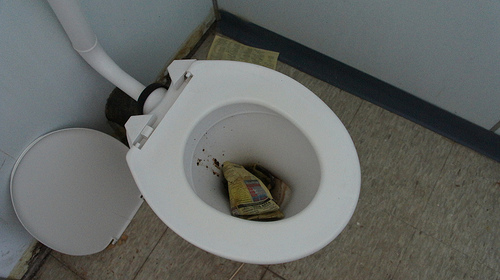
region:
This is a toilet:
[116, 48, 373, 271]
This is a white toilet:
[119, 38, 370, 271]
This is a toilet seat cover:
[3, 125, 150, 261]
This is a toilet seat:
[137, 60, 357, 264]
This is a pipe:
[53, 3, 152, 108]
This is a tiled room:
[5, 10, 499, 276]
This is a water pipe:
[50, 2, 159, 113]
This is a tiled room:
[212, 2, 498, 115]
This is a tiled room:
[1, 1, 208, 173]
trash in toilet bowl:
[185, 125, 320, 227]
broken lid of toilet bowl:
[4, 118, 149, 253]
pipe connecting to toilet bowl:
[44, 2, 164, 105]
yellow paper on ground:
[201, 31, 296, 77]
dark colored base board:
[218, 14, 496, 170]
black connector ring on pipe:
[126, 83, 168, 108]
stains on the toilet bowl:
[195, 141, 230, 176]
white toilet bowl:
[112, 57, 364, 269]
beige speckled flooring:
[46, 25, 498, 277]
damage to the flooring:
[7, 239, 63, 275]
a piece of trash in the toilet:
[219, 156, 288, 223]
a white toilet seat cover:
[12, 123, 148, 255]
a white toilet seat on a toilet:
[125, 53, 360, 263]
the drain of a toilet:
[217, 155, 289, 213]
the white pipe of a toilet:
[50, 1, 170, 113]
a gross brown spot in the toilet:
[192, 133, 227, 184]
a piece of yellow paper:
[207, 31, 280, 69]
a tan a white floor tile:
[346, 96, 456, 225]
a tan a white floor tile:
[416, 141, 498, 263]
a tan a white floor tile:
[296, 199, 403, 279]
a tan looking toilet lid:
[5, 126, 147, 256]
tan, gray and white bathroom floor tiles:
[368, 158, 494, 277]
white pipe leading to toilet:
[51, 1, 168, 116]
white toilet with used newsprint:
[127, 58, 363, 263]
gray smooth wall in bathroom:
[377, 1, 496, 83]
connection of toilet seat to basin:
[120, 56, 193, 147]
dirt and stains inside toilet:
[186, 129, 223, 188]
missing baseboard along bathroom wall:
[20, 244, 50, 278]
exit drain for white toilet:
[99, 85, 142, 135]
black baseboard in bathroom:
[400, 109, 495, 166]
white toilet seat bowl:
[123, 49, 365, 266]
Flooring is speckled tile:
[23, 30, 499, 279]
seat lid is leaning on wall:
[9, 123, 149, 257]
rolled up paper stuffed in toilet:
[212, 152, 293, 219]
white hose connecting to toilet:
[47, 0, 167, 129]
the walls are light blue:
[1, 1, 498, 278]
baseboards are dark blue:
[208, 5, 498, 164]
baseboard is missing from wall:
[0, 7, 217, 274]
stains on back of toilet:
[195, 143, 229, 188]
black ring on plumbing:
[133, 78, 168, 110]